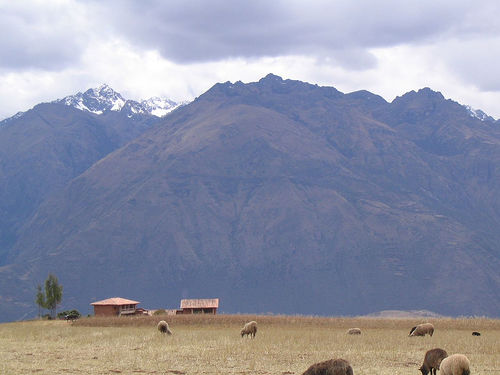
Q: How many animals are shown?
A: Seven.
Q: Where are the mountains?
A: Background.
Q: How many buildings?
A: Two.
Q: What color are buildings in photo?
A: Red.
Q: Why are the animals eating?
A: Hungry.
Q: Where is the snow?
A: Mountain top.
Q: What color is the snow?
A: White.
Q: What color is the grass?
A: Brown.